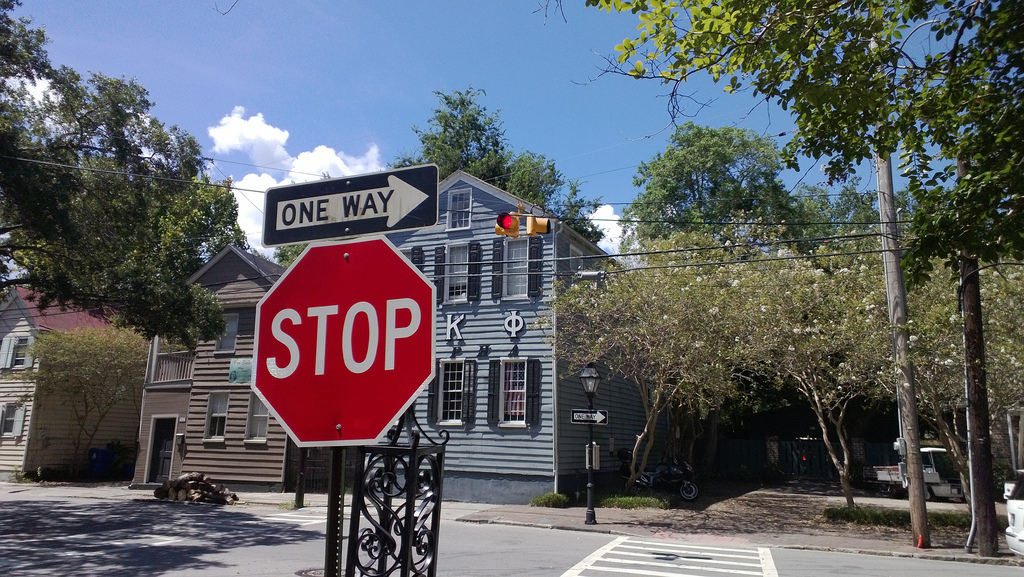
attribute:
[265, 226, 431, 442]
sign — red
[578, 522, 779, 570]
lines — white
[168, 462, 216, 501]
fire wood — pile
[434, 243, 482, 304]
shutters — black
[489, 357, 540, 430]
shutters — black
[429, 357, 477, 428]
shutters — black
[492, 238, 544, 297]
shutters — black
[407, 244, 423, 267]
shutters — black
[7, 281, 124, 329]
roof — red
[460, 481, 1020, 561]
sidewalk — concrete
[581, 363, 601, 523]
light — black, metal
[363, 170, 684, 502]
building — grey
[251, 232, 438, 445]
sign — red, white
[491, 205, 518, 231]
traffic light — yellow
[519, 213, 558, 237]
traffic light — yellow